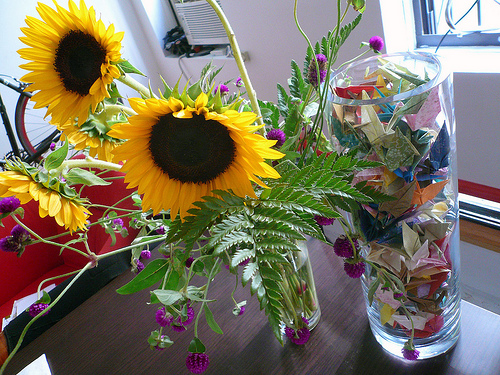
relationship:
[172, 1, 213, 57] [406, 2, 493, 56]
air conditioner in window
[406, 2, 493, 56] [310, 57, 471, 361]
window behind vase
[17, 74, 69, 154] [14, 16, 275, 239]
wheel behind sunflowers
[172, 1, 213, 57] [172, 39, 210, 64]
air conditioner has cord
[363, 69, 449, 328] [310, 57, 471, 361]
origami in vase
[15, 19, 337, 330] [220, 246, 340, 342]
flowers in vase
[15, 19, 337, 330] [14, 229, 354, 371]
flowers on table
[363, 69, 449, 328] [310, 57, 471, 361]
origami inside vase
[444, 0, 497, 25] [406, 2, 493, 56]
light through window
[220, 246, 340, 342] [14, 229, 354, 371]
vase on table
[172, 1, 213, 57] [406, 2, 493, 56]
air conditioner inside window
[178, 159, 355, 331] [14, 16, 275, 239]
leaves next to sunflowers